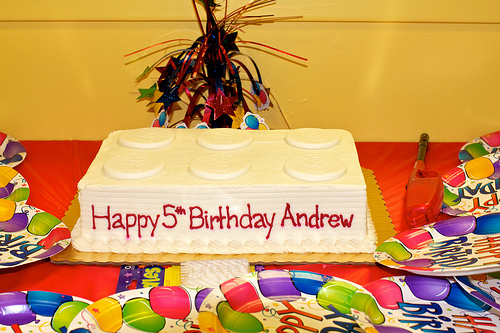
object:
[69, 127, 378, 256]
birthday cake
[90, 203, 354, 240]
letter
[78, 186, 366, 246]
icing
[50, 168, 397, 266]
tray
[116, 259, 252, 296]
candles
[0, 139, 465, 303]
cloth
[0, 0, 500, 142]
wall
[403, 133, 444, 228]
lighter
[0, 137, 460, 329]
table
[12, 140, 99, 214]
tablecloth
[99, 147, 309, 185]
frosting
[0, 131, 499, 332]
plate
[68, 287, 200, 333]
design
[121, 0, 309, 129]
fountain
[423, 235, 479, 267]
words